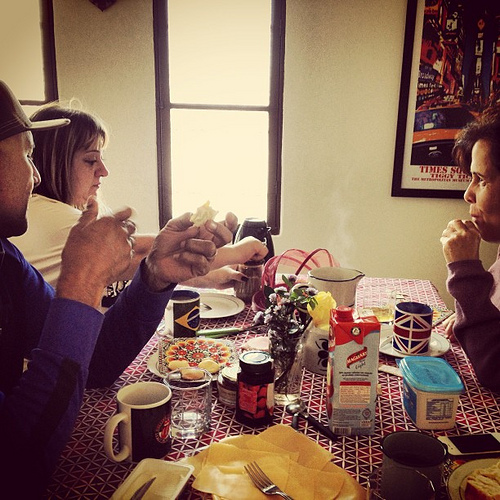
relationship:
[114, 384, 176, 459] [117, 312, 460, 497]
mug on table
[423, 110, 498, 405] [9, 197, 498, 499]
person sitting around table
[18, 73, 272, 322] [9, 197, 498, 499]
person sitting around table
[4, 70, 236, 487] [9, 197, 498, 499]
person sitting around table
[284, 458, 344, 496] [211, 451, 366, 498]
napkin on plate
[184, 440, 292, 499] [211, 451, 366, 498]
napkin on plate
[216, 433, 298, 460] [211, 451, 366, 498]
napkin on plate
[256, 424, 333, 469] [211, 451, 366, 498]
napkin on plate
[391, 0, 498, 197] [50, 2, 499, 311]
picture on wall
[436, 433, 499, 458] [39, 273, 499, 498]
cell phone on table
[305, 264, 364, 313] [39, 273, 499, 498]
pitcher on table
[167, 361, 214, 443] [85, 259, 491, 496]
glass on table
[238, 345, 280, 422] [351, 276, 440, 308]
jelly jar on table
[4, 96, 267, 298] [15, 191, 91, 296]
person in shirt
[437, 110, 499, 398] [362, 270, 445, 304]
person sitting around table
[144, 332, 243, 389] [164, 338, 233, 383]
plate on cookies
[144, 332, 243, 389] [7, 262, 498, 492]
plate on table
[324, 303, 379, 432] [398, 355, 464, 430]
carton of butter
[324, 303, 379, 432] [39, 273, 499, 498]
carton on table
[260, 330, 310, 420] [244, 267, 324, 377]
vase of flowers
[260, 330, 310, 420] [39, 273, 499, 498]
vase on table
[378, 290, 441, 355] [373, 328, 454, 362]
mug on plate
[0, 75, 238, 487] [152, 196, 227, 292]
person holding piece bread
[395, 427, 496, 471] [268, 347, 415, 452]
cell phone on table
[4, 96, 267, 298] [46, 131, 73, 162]
person has brown hair